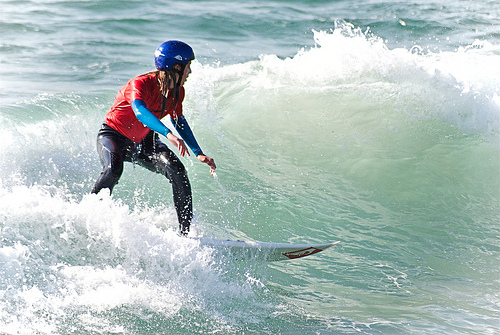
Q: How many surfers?
A: 1.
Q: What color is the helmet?
A: Blue.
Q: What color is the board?
A: White.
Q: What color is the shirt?
A: Red.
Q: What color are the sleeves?
A: Blue.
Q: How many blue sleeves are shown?
A: 2.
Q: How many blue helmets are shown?
A: 1.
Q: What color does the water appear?
A: Green.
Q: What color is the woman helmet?
A: Blue.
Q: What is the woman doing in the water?
A: Surfboarding.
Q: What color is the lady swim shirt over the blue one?
A: Red.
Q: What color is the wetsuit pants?
A: Black.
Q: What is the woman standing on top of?
A: Surfboard.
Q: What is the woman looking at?
A: Waves.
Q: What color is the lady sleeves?
A: Blue.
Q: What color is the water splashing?
A: White.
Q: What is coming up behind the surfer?
A: Wave.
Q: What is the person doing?
A: Surfing.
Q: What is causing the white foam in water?
A: Crashing waves.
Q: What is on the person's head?
A: Helmet.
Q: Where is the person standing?
A: On surfboard.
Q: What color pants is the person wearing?
A: Black.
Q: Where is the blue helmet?
A: On surfer's head.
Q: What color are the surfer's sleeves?
A: Light blue.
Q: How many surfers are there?
A: 1.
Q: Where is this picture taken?
A: Ocean.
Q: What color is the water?
A: Blue.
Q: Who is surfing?
A: The man.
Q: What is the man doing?
A: Surfing.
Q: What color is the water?
A: Blue.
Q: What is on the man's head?
A: A helmet.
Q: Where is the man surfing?
A: In the ocean.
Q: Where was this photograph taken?
A: The Ocean.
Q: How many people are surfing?
A: One.